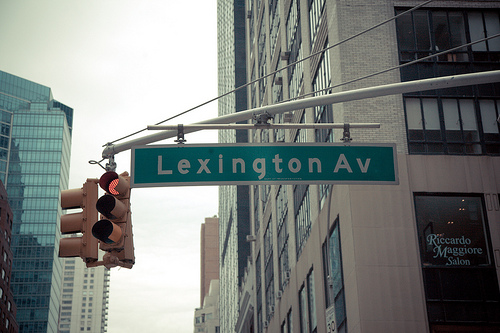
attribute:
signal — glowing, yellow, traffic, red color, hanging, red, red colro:
[92, 170, 135, 269]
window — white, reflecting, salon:
[416, 192, 498, 321]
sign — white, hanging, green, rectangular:
[131, 143, 400, 186]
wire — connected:
[90, 155, 108, 169]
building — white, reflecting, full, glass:
[242, 2, 499, 330]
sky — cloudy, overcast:
[2, 1, 221, 332]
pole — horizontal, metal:
[102, 67, 495, 159]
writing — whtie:
[157, 155, 171, 175]